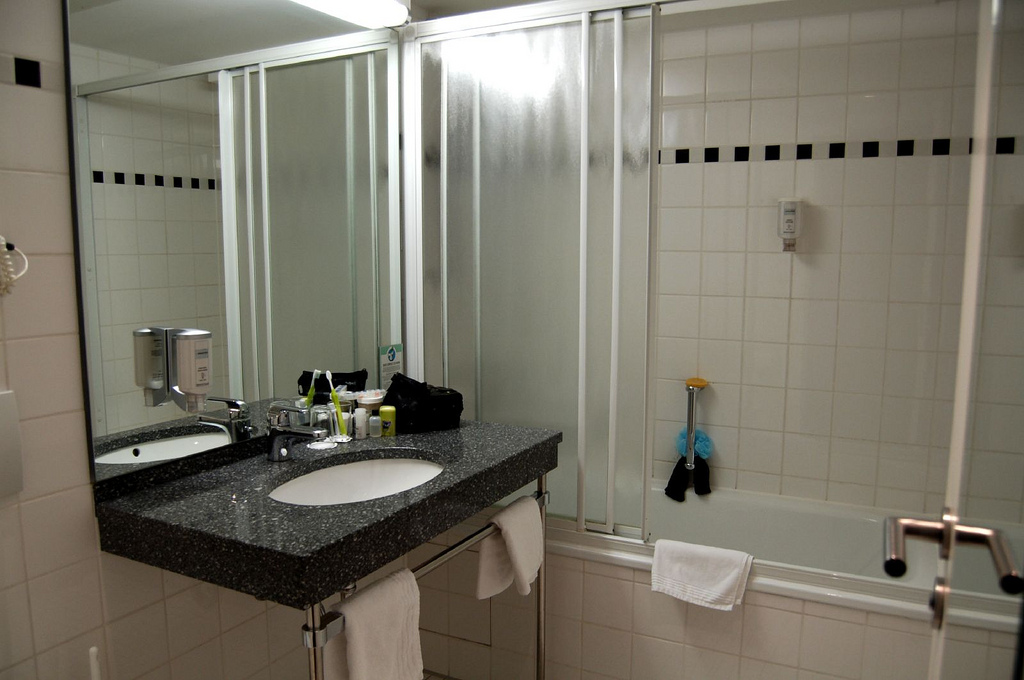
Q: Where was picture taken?
A: In a bathroom.